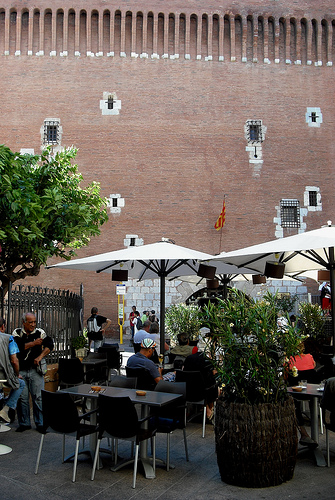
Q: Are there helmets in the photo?
A: No, there are no helmets.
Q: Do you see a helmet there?
A: No, there are no helmets.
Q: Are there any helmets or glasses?
A: No, there are no helmets or glasses.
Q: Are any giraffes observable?
A: No, there are no giraffes.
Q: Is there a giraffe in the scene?
A: No, there are no giraffes.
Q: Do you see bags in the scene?
A: No, there are no bags.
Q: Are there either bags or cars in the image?
A: No, there are no bags or cars.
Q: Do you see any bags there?
A: No, there are no bags.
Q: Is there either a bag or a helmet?
A: No, there are no bags or helmets.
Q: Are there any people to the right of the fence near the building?
A: Yes, there is a person to the right of the fence.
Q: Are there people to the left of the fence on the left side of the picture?
A: No, the person is to the right of the fence.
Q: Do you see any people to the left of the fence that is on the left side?
A: No, the person is to the right of the fence.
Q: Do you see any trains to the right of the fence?
A: No, there is a person to the right of the fence.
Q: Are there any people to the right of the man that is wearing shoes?
A: Yes, there is a person to the right of the man.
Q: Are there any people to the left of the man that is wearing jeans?
A: No, the person is to the right of the man.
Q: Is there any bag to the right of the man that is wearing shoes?
A: No, there is a person to the right of the man.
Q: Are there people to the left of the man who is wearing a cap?
A: Yes, there is a person to the left of the man.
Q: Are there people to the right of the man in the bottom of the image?
A: No, the person is to the left of the man.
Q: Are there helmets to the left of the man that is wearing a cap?
A: No, there is a person to the left of the man.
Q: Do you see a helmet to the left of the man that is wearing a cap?
A: No, there is a person to the left of the man.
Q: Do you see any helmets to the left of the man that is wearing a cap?
A: No, there is a person to the left of the man.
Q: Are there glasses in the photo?
A: No, there are no glasses.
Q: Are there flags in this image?
A: Yes, there is a flag.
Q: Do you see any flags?
A: Yes, there is a flag.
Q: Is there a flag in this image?
A: Yes, there is a flag.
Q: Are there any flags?
A: Yes, there is a flag.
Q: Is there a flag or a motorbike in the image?
A: Yes, there is a flag.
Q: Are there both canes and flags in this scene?
A: No, there is a flag but no canes.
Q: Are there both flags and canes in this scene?
A: No, there is a flag but no canes.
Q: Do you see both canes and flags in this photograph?
A: No, there is a flag but no canes.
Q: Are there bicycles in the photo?
A: No, there are no bicycles.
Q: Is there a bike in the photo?
A: No, there are no bikes.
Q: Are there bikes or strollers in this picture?
A: No, there are no bikes or strollers.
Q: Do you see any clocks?
A: No, there are no clocks.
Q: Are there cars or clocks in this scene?
A: No, there are no clocks or cars.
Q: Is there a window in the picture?
A: Yes, there is a window.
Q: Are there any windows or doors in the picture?
A: Yes, there is a window.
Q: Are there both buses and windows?
A: No, there is a window but no buses.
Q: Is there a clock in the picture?
A: No, there are no clocks.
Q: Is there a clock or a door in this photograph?
A: No, there are no clocks or doors.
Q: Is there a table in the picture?
A: Yes, there is a table.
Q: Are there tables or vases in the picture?
A: Yes, there is a table.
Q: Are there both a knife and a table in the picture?
A: No, there is a table but no knives.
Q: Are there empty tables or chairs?
A: Yes, there is an empty table.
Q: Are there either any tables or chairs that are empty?
A: Yes, the table is empty.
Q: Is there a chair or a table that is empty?
A: Yes, the table is empty.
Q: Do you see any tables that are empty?
A: Yes, there is an empty table.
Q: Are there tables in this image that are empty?
A: Yes, there is a table that is empty.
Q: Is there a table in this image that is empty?
A: Yes, there is a table that is empty.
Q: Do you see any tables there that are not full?
A: Yes, there is a empty table.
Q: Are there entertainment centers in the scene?
A: No, there are no entertainment centers.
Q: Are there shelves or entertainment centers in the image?
A: No, there are no entertainment centers or shelves.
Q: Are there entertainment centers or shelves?
A: No, there are no entertainment centers or shelves.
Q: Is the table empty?
A: Yes, the table is empty.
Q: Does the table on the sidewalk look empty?
A: Yes, the table is empty.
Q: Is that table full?
A: No, the table is empty.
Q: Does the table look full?
A: No, the table is empty.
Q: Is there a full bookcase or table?
A: No, there is a table but it is empty.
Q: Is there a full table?
A: No, there is a table but it is empty.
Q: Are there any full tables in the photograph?
A: No, there is a table but it is empty.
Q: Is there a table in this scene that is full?
A: No, there is a table but it is empty.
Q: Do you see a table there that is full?
A: No, there is a table but it is empty.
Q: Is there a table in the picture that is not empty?
A: No, there is a table but it is empty.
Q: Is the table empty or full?
A: The table is empty.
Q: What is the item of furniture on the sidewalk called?
A: The piece of furniture is a table.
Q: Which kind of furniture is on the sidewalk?
A: The piece of furniture is a table.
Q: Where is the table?
A: The table is on the sidewalk.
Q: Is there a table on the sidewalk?
A: Yes, there is a table on the sidewalk.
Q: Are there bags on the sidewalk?
A: No, there is a table on the sidewalk.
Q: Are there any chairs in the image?
A: Yes, there is a chair.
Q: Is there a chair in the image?
A: Yes, there is a chair.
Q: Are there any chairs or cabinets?
A: Yes, there is a chair.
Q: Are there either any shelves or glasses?
A: No, there are no glasses or shelves.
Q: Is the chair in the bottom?
A: Yes, the chair is in the bottom of the image.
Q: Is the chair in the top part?
A: No, the chair is in the bottom of the image.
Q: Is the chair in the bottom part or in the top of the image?
A: The chair is in the bottom of the image.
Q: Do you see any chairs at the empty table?
A: Yes, there is a chair at the table.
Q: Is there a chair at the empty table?
A: Yes, there is a chair at the table.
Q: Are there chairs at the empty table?
A: Yes, there is a chair at the table.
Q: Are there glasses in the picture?
A: No, there are no glasses.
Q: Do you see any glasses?
A: No, there are no glasses.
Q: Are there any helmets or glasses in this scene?
A: No, there are no glasses or helmets.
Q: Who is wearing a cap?
A: The man is wearing a cap.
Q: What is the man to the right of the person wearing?
A: The man is wearing a cap.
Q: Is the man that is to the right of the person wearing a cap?
A: Yes, the man is wearing a cap.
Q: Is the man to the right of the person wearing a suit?
A: No, the man is wearing a cap.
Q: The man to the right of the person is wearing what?
A: The man is wearing a cap.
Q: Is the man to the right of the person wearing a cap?
A: Yes, the man is wearing a cap.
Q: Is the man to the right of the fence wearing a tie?
A: No, the man is wearing a cap.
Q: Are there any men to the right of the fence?
A: Yes, there is a man to the right of the fence.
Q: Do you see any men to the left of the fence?
A: No, the man is to the right of the fence.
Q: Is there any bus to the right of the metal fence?
A: No, there is a man to the right of the fence.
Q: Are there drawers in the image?
A: No, there are no drawers.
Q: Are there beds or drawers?
A: No, there are no drawers or beds.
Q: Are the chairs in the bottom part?
A: Yes, the chairs are in the bottom of the image.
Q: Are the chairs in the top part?
A: No, the chairs are in the bottom of the image.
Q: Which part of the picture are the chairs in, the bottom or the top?
A: The chairs are in the bottom of the image.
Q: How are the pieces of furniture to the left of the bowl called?
A: The pieces of furniture are chairs.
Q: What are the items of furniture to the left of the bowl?
A: The pieces of furniture are chairs.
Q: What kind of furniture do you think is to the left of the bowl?
A: The pieces of furniture are chairs.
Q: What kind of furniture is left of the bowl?
A: The pieces of furniture are chairs.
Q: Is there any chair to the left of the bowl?
A: Yes, there are chairs to the left of the bowl.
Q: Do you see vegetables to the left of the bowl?
A: No, there are chairs to the left of the bowl.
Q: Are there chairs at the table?
A: Yes, there are chairs at the table.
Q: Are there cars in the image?
A: No, there are no cars.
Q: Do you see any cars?
A: No, there are no cars.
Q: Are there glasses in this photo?
A: No, there are no glasses.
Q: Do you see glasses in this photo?
A: No, there are no glasses.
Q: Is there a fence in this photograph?
A: Yes, there is a fence.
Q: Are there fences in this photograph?
A: Yes, there is a fence.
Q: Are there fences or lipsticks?
A: Yes, there is a fence.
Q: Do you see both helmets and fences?
A: No, there is a fence but no helmets.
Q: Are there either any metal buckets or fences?
A: Yes, there is a metal fence.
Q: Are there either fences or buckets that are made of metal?
A: Yes, the fence is made of metal.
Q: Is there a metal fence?
A: Yes, there is a fence that is made of metal.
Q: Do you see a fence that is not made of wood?
A: Yes, there is a fence that is made of metal.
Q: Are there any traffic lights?
A: No, there are no traffic lights.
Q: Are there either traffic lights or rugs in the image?
A: No, there are no traffic lights or rugs.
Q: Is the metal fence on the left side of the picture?
A: Yes, the fence is on the left of the image.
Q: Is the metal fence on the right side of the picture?
A: No, the fence is on the left of the image.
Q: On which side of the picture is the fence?
A: The fence is on the left of the image.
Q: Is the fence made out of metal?
A: Yes, the fence is made of metal.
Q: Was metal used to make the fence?
A: Yes, the fence is made of metal.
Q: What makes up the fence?
A: The fence is made of metal.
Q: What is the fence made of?
A: The fence is made of metal.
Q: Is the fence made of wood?
A: No, the fence is made of metal.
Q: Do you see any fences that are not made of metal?
A: No, there is a fence but it is made of metal.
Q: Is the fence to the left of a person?
A: Yes, the fence is to the left of a person.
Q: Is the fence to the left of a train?
A: No, the fence is to the left of a person.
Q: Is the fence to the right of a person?
A: No, the fence is to the left of a person.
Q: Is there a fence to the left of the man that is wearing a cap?
A: Yes, there is a fence to the left of the man.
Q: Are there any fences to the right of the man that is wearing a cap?
A: No, the fence is to the left of the man.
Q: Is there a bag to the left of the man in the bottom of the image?
A: No, there is a fence to the left of the man.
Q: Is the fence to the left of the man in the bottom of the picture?
A: Yes, the fence is to the left of the man.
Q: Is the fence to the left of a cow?
A: No, the fence is to the left of the man.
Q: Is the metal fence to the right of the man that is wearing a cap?
A: No, the fence is to the left of the man.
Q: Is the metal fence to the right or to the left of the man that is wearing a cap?
A: The fence is to the left of the man.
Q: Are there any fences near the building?
A: Yes, there is a fence near the building.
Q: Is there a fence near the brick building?
A: Yes, there is a fence near the building.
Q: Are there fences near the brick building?
A: Yes, there is a fence near the building.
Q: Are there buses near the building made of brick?
A: No, there is a fence near the building.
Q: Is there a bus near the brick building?
A: No, there is a fence near the building.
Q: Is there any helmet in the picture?
A: No, there are no helmets.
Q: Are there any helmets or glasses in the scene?
A: No, there are no helmets or glasses.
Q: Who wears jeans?
A: The man wears jeans.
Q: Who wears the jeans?
A: The man wears jeans.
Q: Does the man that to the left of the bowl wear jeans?
A: Yes, the man wears jeans.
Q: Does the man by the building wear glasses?
A: No, the man wears jeans.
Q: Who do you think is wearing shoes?
A: The man is wearing shoes.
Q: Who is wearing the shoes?
A: The man is wearing shoes.